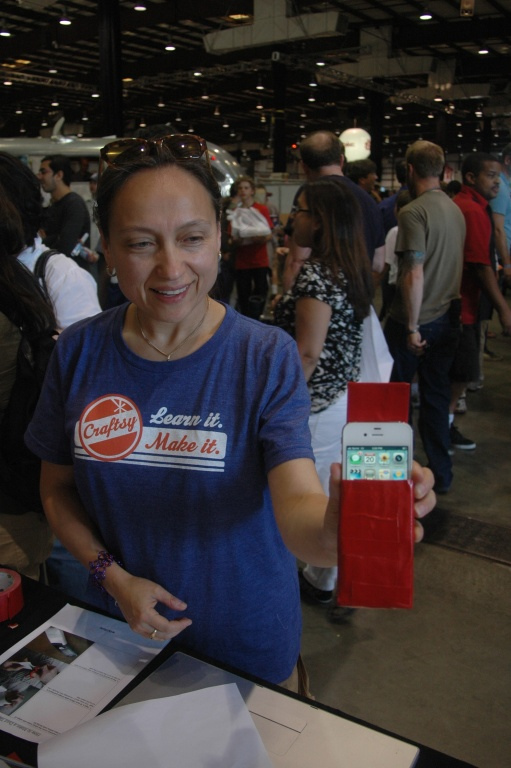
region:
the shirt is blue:
[18, 309, 328, 692]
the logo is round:
[72, 389, 147, 467]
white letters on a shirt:
[146, 399, 237, 434]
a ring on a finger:
[136, 620, 165, 646]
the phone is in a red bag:
[331, 412, 422, 618]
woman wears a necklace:
[39, 125, 285, 433]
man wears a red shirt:
[228, 174, 277, 296]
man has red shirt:
[443, 141, 509, 352]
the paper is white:
[1, 595, 270, 767]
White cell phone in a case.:
[333, 414, 422, 485]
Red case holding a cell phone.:
[325, 365, 419, 611]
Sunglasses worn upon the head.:
[89, 116, 224, 172]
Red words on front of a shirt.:
[75, 368, 155, 470]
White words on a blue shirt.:
[140, 405, 227, 432]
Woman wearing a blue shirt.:
[70, 126, 289, 404]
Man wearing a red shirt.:
[449, 149, 502, 281]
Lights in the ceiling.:
[150, 59, 260, 123]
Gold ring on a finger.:
[143, 621, 164, 642]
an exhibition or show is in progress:
[7, 19, 509, 499]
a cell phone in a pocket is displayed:
[323, 379, 437, 613]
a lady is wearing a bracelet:
[82, 544, 117, 591]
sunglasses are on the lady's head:
[78, 128, 234, 329]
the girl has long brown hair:
[281, 174, 379, 329]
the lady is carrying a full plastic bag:
[223, 176, 277, 327]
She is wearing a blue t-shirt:
[27, 301, 319, 688]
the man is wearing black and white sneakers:
[446, 154, 503, 459]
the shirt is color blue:
[20, 303, 328, 688]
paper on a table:
[0, 598, 275, 767]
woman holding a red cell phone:
[9, 128, 458, 695]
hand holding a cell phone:
[320, 371, 443, 630]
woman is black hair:
[279, 166, 385, 362]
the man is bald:
[289, 119, 387, 256]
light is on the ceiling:
[127, 0, 151, 18]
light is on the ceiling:
[412, 9, 435, 24]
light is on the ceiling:
[253, 79, 270, 93]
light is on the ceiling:
[134, 119, 150, 131]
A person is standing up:
[47, 147, 383, 683]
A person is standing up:
[258, 183, 398, 583]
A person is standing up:
[222, 172, 281, 318]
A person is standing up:
[35, 153, 97, 264]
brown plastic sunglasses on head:
[89, 130, 218, 177]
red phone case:
[337, 371, 417, 603]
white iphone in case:
[339, 420, 420, 484]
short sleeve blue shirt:
[30, 289, 329, 681]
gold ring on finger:
[140, 623, 162, 643]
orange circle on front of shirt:
[75, 382, 144, 462]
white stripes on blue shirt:
[72, 415, 235, 481]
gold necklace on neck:
[131, 323, 207, 364]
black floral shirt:
[270, 247, 366, 414]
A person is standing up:
[43, 164, 321, 698]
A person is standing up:
[282, 134, 389, 309]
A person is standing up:
[342, 157, 384, 216]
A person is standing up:
[384, 150, 461, 486]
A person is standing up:
[22, 149, 107, 263]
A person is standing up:
[1, 197, 66, 589]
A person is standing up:
[387, 164, 428, 209]